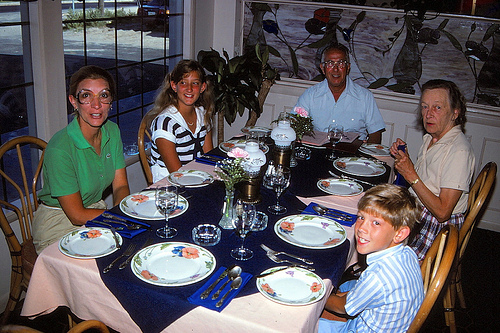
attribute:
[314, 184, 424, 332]
boy — smiling, sitting, young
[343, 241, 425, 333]
shirt — stripped, blue, white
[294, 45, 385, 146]
man — tan, sitting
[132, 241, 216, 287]
plate — fancy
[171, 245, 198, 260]
flower — pink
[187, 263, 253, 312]
napkin — blue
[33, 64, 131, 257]
lady — sitting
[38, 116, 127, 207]
shirt — green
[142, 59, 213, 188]
girl — smiling, sitting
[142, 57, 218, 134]
hair — long, blonde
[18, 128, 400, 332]
tablecloth — pink, blue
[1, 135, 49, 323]
chair — wood, wicker, wooden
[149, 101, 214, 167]
shirt — striped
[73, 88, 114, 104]
glasses — big, large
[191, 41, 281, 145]
plant — tree, standing, artificial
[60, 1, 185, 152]
window — glass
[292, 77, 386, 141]
shirt — blue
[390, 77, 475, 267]
grandma — sitting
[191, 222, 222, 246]
ashtray — clear, glass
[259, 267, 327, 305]
plate — floral print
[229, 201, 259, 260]
goblet — empty